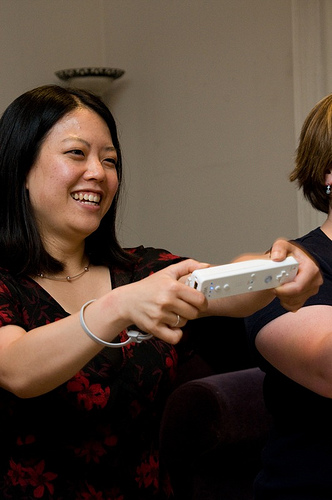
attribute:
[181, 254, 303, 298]
controller — long, white, wrapped, light, wii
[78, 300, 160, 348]
strap — white, wrap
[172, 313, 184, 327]
ring — silver, bright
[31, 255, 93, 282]
necklace — silver, beaded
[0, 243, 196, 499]
shirt — black, red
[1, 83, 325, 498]
woman — happy, smiling, laughing, sitting, playing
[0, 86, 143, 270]
hair — long, black, dark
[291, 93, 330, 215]
hair — short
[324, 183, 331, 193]
earring — silver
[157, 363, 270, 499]
chair — black, purple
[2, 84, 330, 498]
women — laughing, playing, sitting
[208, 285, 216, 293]
light — blue